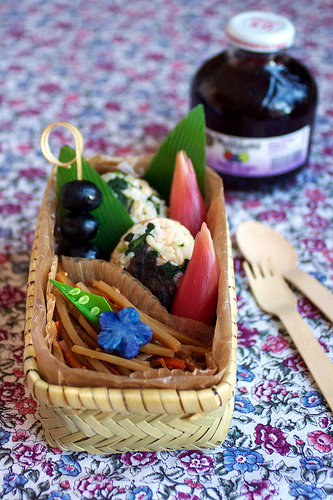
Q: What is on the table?
A: A printed cloth.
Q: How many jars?
A: One.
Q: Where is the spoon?
A: On the table.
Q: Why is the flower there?
A: Decorative.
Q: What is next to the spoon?
A: The fork.